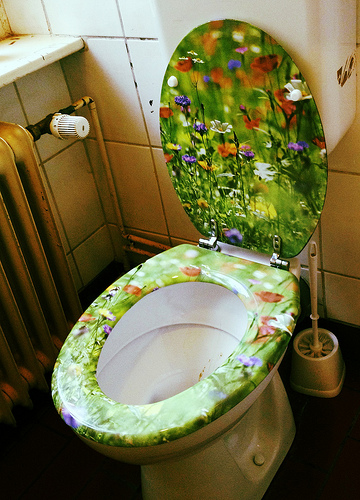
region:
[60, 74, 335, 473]
toilet with garden scene motif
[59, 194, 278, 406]
seat colors on the toilet look worn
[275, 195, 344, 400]
toilet cleaning brush is in the corner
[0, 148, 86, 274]
old fashioned hot water radiator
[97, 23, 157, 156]
white tile behind toilet looks dirty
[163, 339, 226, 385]
bad stain in toilet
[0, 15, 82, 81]
counter top has dirt and rust stains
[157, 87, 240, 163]
purple flowers on toilet seat lid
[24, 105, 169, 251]
rusty pipes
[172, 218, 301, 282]
silver hinges attach lid to seat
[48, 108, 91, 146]
white filtered air freshner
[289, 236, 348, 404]
white toilet brush and it's holder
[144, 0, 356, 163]
water tank to a toilet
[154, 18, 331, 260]
Lid to a toilet seat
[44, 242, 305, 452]
toilet seat in the design of a field of flowers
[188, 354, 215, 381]
orangish brown stain in toilet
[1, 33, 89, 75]
white steel shelf in bathroom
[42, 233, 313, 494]
white bathroom toilet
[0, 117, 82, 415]
radiator heater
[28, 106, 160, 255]
pvc pipe for water plumbing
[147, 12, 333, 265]
a green floral toilet lid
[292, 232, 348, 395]
a white toilet brush cleaner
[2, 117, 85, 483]
a heater vent next to the toilet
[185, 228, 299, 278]
silver latches on the toilet seat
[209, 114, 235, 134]
white flower with yellow center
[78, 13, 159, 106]
dirty grout near the toilet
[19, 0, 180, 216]
white tiles make up the wall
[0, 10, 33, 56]
rust stain in a corner of the bathroom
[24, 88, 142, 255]
a metal pipe leading to the vent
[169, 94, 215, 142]
purple flowers on the lid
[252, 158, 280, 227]
a flower in a picture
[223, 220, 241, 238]
a flower in a picture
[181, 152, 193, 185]
a flower in a picture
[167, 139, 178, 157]
a flower in a picture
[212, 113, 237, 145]
a flower in a picture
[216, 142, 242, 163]
a flower in a picture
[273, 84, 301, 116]
a flower in a picture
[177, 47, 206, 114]
a flower in a picture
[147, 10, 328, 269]
a colored toilet seat cover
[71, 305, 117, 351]
a flower in a picture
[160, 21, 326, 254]
toilet lid printed with photograph of wild flowers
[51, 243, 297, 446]
toilet seat with wild flowers to match lid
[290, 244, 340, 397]
white toilet brush with stand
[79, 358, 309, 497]
traditional white toilet under flowery seat and lid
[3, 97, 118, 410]
old fashioned radiator to heat the bathroom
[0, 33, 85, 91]
edge of white window sill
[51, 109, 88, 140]
knob to turn radiator on and off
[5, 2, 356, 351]
old worn looking white wall tiles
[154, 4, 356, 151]
white tank for flowery toilet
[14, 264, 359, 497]
dark brown flooring